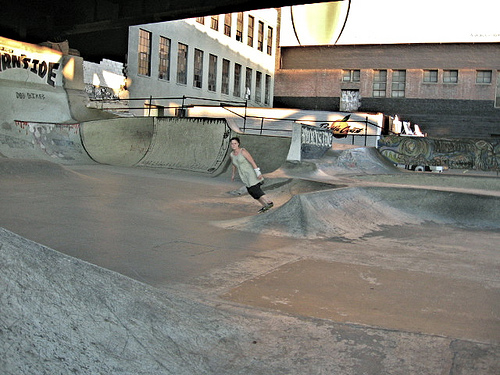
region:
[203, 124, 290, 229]
a girl is skating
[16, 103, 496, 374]
a track skating near buidings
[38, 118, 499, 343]
girl in a track skating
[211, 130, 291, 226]
girl wears green top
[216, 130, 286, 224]
girl wears black pants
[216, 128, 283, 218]
woman has a wrist band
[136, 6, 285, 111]
a building near a track skating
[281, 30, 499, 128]
a red brick on front a track skating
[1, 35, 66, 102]
black letters in front a track skating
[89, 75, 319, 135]
a ramp on side track skating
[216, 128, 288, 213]
person skateboarding on ramp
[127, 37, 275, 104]
windows on the building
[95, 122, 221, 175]
gray ramps on the ground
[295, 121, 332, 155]
words on the sign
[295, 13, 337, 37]
yellow on the roof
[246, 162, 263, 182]
white wristband on the wrist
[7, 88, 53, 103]
words on the wall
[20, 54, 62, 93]
word side on the wall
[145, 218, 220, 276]
gray square on the ground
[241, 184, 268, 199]
black shorts on the person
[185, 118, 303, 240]
a woman is skateboarding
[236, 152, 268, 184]
the woman`s wrist is bandaged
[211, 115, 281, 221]
the woman is leaning left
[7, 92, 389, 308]
the woman is at a skate park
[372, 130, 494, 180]
a mural on the wall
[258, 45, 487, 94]
the building is brown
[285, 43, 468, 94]
the building is made of bricks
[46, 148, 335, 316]
the ground is grey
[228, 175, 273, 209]
the woman`s pants are black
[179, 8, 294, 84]
the sun is on the building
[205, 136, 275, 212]
female skateboarder in urban skate park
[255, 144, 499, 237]
features in skateboard park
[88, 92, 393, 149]
railings in skateboard park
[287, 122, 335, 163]
name of skateboard park painted on a traffic barrier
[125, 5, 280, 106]
commercial industrial building with broken windows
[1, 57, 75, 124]
Skatepark name Burnside painted onto park wall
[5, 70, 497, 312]
solitary skateboarder has skate park all to herelf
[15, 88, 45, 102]
sign about bikes painted on skate park wall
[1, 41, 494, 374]
solitary skateboarder in bleak skate park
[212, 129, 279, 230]
girl on skateboard in the skate park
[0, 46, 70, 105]
painting on wall at skate park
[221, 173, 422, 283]
cement paved ramps for skateboarding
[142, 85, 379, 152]
metal railing around the skate park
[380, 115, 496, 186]
graffiti painted on walls of skate park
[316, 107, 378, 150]
orange and green fruit painted on trailer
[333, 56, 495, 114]
glass windows on brick building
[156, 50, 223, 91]
windows missing small panes of glass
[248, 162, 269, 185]
white bandages wrapped around left wrist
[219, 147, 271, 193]
long gray tank top on skater